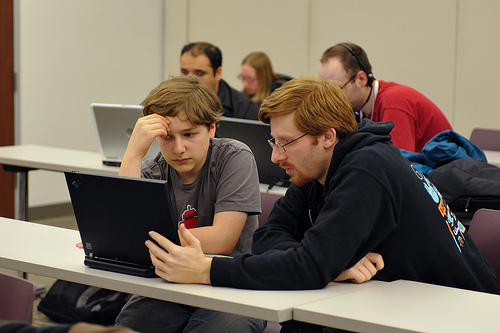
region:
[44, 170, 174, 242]
open black laptop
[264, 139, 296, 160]
glasses worn by man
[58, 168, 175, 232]
open black colored computer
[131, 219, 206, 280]
left hand of man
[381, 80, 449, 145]
red sweater worn by man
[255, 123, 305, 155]
brown eyeglasses worn by man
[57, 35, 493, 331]
people sitting in a room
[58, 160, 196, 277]
a laptop on table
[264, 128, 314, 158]
eyeglasses the guy is wearing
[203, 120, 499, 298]
a hoodie the guy is wearing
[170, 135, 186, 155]
a nose of the person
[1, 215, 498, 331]
a long table in the room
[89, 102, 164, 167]
a laptop the guy is using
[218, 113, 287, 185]
a laptop the guy is using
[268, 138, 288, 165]
a nose of the guy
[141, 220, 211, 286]
a hand of a white person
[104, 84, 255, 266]
a person looking at a computer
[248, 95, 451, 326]
a person looking at a computer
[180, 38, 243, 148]
a person looking at a computer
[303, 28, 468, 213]
a person looking at a computer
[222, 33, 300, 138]
a person looking at a computer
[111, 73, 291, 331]
a person sitting at a table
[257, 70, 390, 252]
a person sitting at a table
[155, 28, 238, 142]
a person sitting at a table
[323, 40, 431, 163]
a person sitting at a table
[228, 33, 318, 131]
a person sitting at a table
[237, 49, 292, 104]
girl with long hair wearing glasses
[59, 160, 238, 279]
open black laptop computer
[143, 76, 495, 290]
red haired boy wearing glasses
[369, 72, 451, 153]
red shirt with white collar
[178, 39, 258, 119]
man in black shirt with black receding hairline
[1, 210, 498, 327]
long light gray work table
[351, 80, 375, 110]
black string around man's neck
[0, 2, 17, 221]
brown wooden door into room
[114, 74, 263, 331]
boy in gray t-shirt with red emblem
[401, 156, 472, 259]
blue and orange design on hoodie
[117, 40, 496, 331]
a group of people in a classroom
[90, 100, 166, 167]
silver Dell laptop in the back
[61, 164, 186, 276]
a black ibm laptop in the front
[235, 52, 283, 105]
a female in the back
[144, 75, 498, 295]
man in the front in a black hoodie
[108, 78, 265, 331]
guy in a gray shirt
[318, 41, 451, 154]
man in a red t-shirt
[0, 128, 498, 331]
group of gray desks and purple chairs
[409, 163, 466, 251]
design on the back of the man's hoodie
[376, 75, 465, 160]
a red sweater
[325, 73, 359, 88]
a pair of glasses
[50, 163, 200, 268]
a laptop on the table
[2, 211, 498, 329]
the first table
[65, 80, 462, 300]
Two people looking at the same laptop.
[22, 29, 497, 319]
A classroom setting.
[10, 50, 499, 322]
People sitting at long tables.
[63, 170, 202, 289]
A black laptop computer on the table.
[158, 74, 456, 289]
the man in the glasses is touching the laptop.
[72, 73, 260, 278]
The boy in the grey shirt is looking at the laptop.